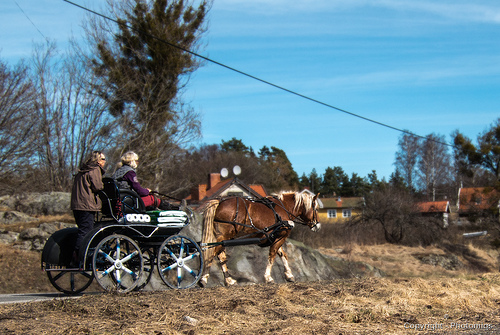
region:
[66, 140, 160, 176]
face of the person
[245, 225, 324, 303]
front legs of the horse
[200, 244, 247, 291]
back legs of the horse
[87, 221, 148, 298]
wheel of the cart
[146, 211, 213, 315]
front wheel of the vehicle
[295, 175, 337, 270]
face of the horse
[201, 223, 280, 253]
a iron stand to hold horse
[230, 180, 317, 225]
threads tied to horse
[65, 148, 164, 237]
two person sitting in car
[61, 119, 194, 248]
two person driving horse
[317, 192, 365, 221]
yellow house in the back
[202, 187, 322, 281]
brown horse with blonde tail and mane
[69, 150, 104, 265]
woman standing on the buggy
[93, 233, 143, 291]
wheel whith white and blue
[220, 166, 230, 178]
satellite dish on the roof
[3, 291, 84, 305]
small paved area of road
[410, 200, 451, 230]
small white building with red roof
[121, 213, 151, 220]
package of toilet paper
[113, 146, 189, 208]
blonde woman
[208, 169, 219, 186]
taller brick chimney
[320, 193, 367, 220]
a yellow house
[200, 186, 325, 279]
a brown horse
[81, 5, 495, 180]
a black wire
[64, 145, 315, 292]
a horse carriage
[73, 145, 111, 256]
a person standing on the back of the horse carriage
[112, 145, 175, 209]
a person sitting in the horse carriage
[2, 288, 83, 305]
the road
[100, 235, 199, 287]
wheels on the carriage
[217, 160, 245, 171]
two satellite dishes on the roof of the house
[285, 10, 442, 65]
clouds in the sky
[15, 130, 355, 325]
A horse is pulling a buggy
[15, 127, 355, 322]
The horse is doing some work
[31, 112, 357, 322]
A horse is doing his job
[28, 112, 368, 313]
Two people are riding in a buggy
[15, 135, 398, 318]
Two people are pulled by the horse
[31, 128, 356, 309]
The horse is walking very slowly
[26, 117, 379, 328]
The people are going to town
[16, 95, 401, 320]
The people are enjoying the sunshine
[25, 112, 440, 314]
The people are out in the day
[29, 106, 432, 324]
Some people are enjoying their day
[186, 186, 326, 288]
Brown donkey with white mane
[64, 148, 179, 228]
Two people riding in a cart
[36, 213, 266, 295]
Cart pulled by horse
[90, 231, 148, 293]
Back left wheel with white spokes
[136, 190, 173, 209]
Leg with red pants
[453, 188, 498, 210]
Red roof on a house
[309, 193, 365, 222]
Yellow house with two windows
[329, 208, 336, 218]
Left window with four panes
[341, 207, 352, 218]
Right window with four panes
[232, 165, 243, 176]
Satellite dish on roof